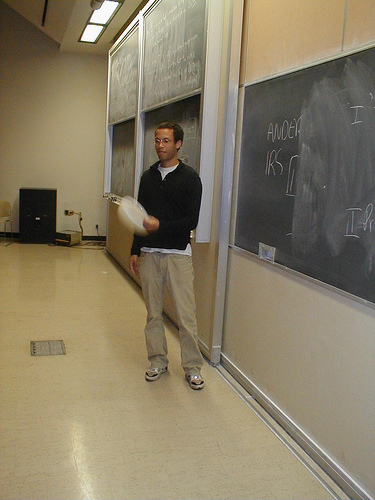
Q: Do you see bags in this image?
A: No, there are no bags.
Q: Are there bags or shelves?
A: No, there are no bags or shelves.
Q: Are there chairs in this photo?
A: Yes, there is a chair.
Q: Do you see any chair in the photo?
A: Yes, there is a chair.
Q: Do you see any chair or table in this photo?
A: Yes, there is a chair.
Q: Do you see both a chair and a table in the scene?
A: No, there is a chair but no tables.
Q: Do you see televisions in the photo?
A: No, there are no televisions.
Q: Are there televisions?
A: No, there are no televisions.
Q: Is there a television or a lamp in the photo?
A: No, there are no televisions or lamps.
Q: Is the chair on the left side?
A: Yes, the chair is on the left of the image.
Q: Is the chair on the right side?
A: No, the chair is on the left of the image.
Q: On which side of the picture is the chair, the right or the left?
A: The chair is on the left of the image.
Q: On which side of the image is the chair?
A: The chair is on the left of the image.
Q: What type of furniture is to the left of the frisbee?
A: The piece of furniture is a chair.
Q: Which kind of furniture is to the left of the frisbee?
A: The piece of furniture is a chair.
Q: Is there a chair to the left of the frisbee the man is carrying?
A: Yes, there is a chair to the left of the frisbee.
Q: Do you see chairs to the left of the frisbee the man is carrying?
A: Yes, there is a chair to the left of the frisbee.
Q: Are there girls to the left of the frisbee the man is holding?
A: No, there is a chair to the left of the frisbee.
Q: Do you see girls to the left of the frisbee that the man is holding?
A: No, there is a chair to the left of the frisbee.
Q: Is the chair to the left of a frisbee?
A: Yes, the chair is to the left of a frisbee.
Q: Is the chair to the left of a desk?
A: No, the chair is to the left of a frisbee.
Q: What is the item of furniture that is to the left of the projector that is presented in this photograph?
A: The piece of furniture is a chair.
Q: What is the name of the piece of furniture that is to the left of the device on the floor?
A: The piece of furniture is a chair.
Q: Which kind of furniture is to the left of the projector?
A: The piece of furniture is a chair.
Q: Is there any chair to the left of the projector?
A: Yes, there is a chair to the left of the projector.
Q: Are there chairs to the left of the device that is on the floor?
A: Yes, there is a chair to the left of the projector.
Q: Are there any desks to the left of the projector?
A: No, there is a chair to the left of the projector.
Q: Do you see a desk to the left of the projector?
A: No, there is a chair to the left of the projector.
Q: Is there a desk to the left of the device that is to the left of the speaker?
A: No, there is a chair to the left of the projector.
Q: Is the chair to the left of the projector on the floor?
A: Yes, the chair is to the left of the projector.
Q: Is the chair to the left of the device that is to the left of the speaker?
A: Yes, the chair is to the left of the projector.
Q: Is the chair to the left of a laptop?
A: No, the chair is to the left of the projector.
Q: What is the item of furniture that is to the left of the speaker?
A: The piece of furniture is a chair.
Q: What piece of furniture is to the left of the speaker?
A: The piece of furniture is a chair.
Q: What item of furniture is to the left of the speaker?
A: The piece of furniture is a chair.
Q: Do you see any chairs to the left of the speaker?
A: Yes, there is a chair to the left of the speaker.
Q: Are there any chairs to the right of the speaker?
A: No, the chair is to the left of the speaker.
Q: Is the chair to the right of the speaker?
A: No, the chair is to the left of the speaker.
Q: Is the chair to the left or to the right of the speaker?
A: The chair is to the left of the speaker.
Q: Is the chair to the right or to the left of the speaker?
A: The chair is to the left of the speaker.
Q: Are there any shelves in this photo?
A: No, there are no shelves.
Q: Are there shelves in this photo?
A: No, there are no shelves.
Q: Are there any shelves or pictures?
A: No, there are no shelves or pictures.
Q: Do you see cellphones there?
A: No, there are no cellphones.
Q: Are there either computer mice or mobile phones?
A: No, there are no mobile phones or computer mice.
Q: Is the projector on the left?
A: Yes, the projector is on the left of the image.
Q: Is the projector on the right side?
A: No, the projector is on the left of the image.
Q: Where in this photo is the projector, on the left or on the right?
A: The projector is on the left of the image.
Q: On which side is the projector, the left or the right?
A: The projector is on the left of the image.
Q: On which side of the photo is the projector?
A: The projector is on the left of the image.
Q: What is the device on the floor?
A: The device is a projector.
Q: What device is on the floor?
A: The device is a projector.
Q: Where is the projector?
A: The projector is on the floor.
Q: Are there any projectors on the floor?
A: Yes, there is a projector on the floor.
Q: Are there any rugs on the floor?
A: No, there is a projector on the floor.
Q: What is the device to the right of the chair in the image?
A: The device is a projector.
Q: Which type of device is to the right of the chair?
A: The device is a projector.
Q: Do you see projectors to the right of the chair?
A: Yes, there is a projector to the right of the chair.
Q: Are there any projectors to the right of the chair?
A: Yes, there is a projector to the right of the chair.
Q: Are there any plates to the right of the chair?
A: No, there is a projector to the right of the chair.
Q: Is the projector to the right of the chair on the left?
A: Yes, the projector is to the right of the chair.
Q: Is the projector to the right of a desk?
A: No, the projector is to the right of the chair.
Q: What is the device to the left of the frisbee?
A: The device is a projector.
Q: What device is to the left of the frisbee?
A: The device is a projector.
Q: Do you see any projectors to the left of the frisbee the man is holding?
A: Yes, there is a projector to the left of the frisbee.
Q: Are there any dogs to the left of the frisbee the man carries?
A: No, there is a projector to the left of the frisbee.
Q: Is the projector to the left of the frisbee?
A: Yes, the projector is to the left of the frisbee.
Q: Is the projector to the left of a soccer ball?
A: No, the projector is to the left of the frisbee.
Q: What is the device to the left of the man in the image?
A: The device is a projector.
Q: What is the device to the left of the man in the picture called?
A: The device is a projector.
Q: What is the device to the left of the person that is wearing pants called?
A: The device is a projector.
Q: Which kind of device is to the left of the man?
A: The device is a projector.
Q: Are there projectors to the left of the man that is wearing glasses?
A: Yes, there is a projector to the left of the man.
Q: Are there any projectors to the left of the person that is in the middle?
A: Yes, there is a projector to the left of the man.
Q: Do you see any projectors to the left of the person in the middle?
A: Yes, there is a projector to the left of the man.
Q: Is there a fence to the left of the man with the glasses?
A: No, there is a projector to the left of the man.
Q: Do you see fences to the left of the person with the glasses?
A: No, there is a projector to the left of the man.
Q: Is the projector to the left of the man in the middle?
A: Yes, the projector is to the left of the man.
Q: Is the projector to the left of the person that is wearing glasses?
A: Yes, the projector is to the left of the man.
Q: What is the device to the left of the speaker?
A: The device is a projector.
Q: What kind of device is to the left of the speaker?
A: The device is a projector.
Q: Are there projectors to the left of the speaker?
A: Yes, there is a projector to the left of the speaker.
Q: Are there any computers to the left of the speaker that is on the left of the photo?
A: No, there is a projector to the left of the speaker.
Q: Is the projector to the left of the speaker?
A: Yes, the projector is to the left of the speaker.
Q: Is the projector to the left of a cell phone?
A: No, the projector is to the left of the speaker.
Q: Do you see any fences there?
A: No, there are no fences.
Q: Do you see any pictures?
A: No, there are no pictures.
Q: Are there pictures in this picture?
A: No, there are no pictures.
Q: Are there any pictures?
A: No, there are no pictures.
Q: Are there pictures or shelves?
A: No, there are no pictures or shelves.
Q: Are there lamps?
A: No, there are no lamps.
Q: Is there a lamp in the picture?
A: No, there are no lamps.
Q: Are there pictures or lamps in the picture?
A: No, there are no lamps or pictures.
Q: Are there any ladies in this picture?
A: No, there are no ladies.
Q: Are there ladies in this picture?
A: No, there are no ladies.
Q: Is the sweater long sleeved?
A: Yes, the sweater is long sleeved.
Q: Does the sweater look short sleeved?
A: No, the sweater is long sleeved.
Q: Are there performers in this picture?
A: No, there are no performers.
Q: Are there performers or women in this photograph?
A: No, there are no performers or women.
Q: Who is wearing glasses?
A: The man is wearing glasses.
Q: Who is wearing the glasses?
A: The man is wearing glasses.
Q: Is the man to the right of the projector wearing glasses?
A: Yes, the man is wearing glasses.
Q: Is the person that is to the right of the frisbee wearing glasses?
A: Yes, the man is wearing glasses.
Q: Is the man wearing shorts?
A: No, the man is wearing glasses.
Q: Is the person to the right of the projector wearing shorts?
A: No, the man is wearing glasses.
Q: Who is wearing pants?
A: The man is wearing pants.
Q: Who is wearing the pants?
A: The man is wearing pants.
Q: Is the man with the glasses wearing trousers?
A: Yes, the man is wearing trousers.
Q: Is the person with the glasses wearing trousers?
A: Yes, the man is wearing trousers.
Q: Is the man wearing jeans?
A: No, the man is wearing trousers.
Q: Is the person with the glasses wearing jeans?
A: No, the man is wearing trousers.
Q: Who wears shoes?
A: The man wears shoes.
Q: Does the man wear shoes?
A: Yes, the man wears shoes.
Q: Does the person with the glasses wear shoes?
A: Yes, the man wears shoes.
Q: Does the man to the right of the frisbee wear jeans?
A: No, the man wears shoes.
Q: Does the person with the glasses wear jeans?
A: No, the man wears shoes.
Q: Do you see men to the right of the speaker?
A: Yes, there is a man to the right of the speaker.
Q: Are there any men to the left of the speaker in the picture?
A: No, the man is to the right of the speaker.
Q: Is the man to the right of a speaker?
A: Yes, the man is to the right of a speaker.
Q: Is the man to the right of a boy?
A: No, the man is to the right of a speaker.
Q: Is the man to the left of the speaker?
A: No, the man is to the right of the speaker.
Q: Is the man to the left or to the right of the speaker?
A: The man is to the right of the speaker.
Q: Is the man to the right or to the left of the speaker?
A: The man is to the right of the speaker.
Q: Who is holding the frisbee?
A: The man is holding the frisbee.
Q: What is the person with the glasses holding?
A: The man is holding the frisbee.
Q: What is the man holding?
A: The man is holding the frisbee.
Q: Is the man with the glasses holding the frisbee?
A: Yes, the man is holding the frisbee.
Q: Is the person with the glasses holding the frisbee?
A: Yes, the man is holding the frisbee.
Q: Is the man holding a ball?
A: No, the man is holding the frisbee.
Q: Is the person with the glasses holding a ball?
A: No, the man is holding the frisbee.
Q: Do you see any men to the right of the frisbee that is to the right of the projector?
A: Yes, there is a man to the right of the frisbee.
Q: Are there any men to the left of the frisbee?
A: No, the man is to the right of the frisbee.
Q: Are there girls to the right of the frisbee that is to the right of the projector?
A: No, there is a man to the right of the frisbee.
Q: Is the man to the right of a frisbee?
A: Yes, the man is to the right of a frisbee.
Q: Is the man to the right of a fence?
A: No, the man is to the right of a frisbee.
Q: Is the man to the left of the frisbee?
A: No, the man is to the right of the frisbee.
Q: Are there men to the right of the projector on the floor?
A: Yes, there is a man to the right of the projector.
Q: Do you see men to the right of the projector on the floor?
A: Yes, there is a man to the right of the projector.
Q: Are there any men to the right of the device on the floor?
A: Yes, there is a man to the right of the projector.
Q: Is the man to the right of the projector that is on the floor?
A: Yes, the man is to the right of the projector.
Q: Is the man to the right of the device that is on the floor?
A: Yes, the man is to the right of the projector.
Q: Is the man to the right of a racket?
A: No, the man is to the right of the projector.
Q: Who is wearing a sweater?
A: The man is wearing a sweater.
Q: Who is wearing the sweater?
A: The man is wearing a sweater.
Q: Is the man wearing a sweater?
A: Yes, the man is wearing a sweater.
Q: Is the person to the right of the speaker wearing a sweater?
A: Yes, the man is wearing a sweater.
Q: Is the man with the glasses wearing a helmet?
A: No, the man is wearing a sweater.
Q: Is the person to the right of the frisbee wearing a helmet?
A: No, the man is wearing a sweater.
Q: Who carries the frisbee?
A: The man carries the frisbee.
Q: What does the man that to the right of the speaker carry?
A: The man carries a frisbee.